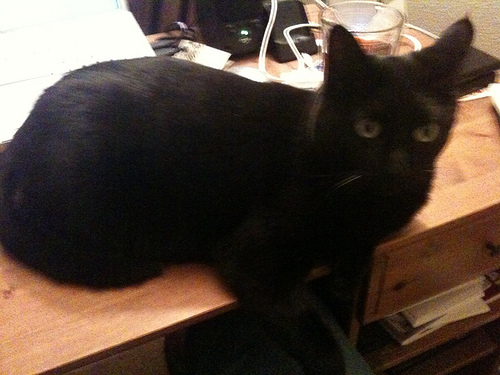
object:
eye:
[356, 117, 382, 140]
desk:
[0, 3, 499, 375]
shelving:
[383, 323, 499, 375]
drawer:
[371, 207, 499, 317]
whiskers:
[335, 175, 363, 190]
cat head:
[321, 15, 473, 197]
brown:
[14, 297, 95, 323]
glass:
[317, 0, 403, 65]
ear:
[323, 23, 369, 92]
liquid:
[352, 38, 390, 62]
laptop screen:
[0, 0, 160, 143]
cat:
[0, 15, 473, 375]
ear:
[414, 15, 473, 71]